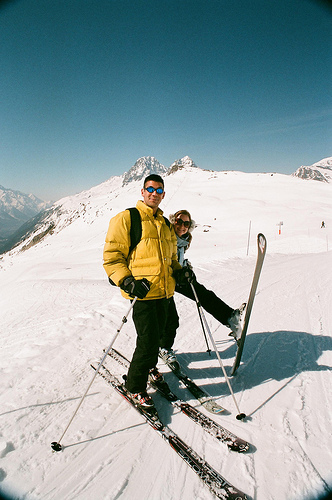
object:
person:
[158, 210, 247, 363]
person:
[321, 221, 325, 229]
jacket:
[102, 200, 181, 301]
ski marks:
[75, 308, 312, 500]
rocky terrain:
[0, 155, 332, 265]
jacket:
[176, 232, 192, 266]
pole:
[58, 297, 138, 444]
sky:
[0, 0, 332, 203]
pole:
[190, 283, 240, 414]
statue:
[103, 173, 196, 408]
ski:
[230, 234, 266, 376]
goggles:
[144, 187, 163, 194]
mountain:
[0, 186, 42, 251]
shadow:
[148, 330, 332, 424]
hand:
[133, 278, 151, 299]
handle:
[125, 296, 137, 318]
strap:
[126, 208, 142, 252]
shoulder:
[117, 206, 146, 220]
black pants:
[127, 296, 179, 395]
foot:
[229, 303, 247, 340]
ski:
[91, 345, 251, 500]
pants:
[158, 277, 233, 351]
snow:
[0, 156, 331, 498]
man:
[103, 174, 196, 407]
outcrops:
[122, 155, 195, 186]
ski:
[158, 351, 225, 414]